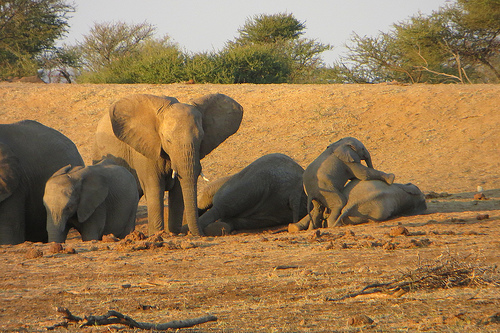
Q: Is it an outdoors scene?
A: Yes, it is outdoors.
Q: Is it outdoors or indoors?
A: It is outdoors.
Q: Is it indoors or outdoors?
A: It is outdoors.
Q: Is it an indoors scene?
A: No, it is outdoors.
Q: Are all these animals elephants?
A: Yes, all the animals are elephants.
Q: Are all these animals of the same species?
A: Yes, all the animals are elephants.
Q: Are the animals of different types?
A: No, all the animals are elephants.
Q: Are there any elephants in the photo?
A: Yes, there is an elephant.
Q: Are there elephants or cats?
A: Yes, there is an elephant.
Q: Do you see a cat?
A: No, there are no cats.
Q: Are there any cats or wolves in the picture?
A: No, there are no cats or wolves.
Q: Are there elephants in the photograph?
A: Yes, there is an elephant.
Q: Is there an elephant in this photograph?
A: Yes, there is an elephant.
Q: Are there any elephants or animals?
A: Yes, there is an elephant.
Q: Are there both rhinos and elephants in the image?
A: No, there is an elephant but no rhinos.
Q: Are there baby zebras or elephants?
A: Yes, there is a baby elephant.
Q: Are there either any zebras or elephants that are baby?
A: Yes, the elephant is a baby.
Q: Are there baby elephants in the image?
A: Yes, there is a baby elephant.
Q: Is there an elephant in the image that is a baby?
A: Yes, there is an elephant that is a baby.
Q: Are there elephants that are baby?
A: Yes, there is an elephant that is a baby.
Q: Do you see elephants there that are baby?
A: Yes, there is an elephant that is a baby.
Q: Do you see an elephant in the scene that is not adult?
A: Yes, there is an baby elephant.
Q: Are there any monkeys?
A: No, there are no monkeys.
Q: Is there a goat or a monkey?
A: No, there are no monkeys or goats.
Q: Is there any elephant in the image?
A: Yes, there is an elephant.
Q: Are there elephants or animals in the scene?
A: Yes, there is an elephant.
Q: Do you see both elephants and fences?
A: No, there is an elephant but no fences.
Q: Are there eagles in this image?
A: No, there are no eagles.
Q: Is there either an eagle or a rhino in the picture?
A: No, there are no eagles or rhinos.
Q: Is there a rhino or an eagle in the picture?
A: No, there are no eagles or rhinos.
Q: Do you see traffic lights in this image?
A: No, there are no traffic lights.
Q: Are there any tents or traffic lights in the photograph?
A: No, there are no traffic lights or tents.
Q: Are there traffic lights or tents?
A: No, there are no traffic lights or tents.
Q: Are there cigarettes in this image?
A: No, there are no cigarettes.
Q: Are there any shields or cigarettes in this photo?
A: No, there are no cigarettes or shields.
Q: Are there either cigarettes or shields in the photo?
A: No, there are no cigarettes or shields.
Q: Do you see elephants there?
A: Yes, there is an elephant.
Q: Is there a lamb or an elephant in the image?
A: Yes, there is an elephant.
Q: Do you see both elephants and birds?
A: No, there is an elephant but no birds.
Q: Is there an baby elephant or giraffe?
A: Yes, there is a baby elephant.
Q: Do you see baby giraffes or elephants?
A: Yes, there is a baby elephant.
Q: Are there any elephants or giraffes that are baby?
A: Yes, the elephant is a baby.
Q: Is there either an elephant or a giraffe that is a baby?
A: Yes, the elephant is a baby.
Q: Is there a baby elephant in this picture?
A: Yes, there is a baby elephant.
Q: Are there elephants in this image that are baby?
A: Yes, there is an elephant that is a baby.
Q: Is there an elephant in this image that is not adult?
A: Yes, there is an baby elephant.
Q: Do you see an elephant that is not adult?
A: Yes, there is an baby elephant.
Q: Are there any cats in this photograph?
A: No, there are no cats.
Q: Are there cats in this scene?
A: No, there are no cats.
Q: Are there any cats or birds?
A: No, there are no cats or birds.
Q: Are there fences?
A: No, there are no fences.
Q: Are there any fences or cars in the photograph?
A: No, there are no fences or cars.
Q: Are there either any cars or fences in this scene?
A: No, there are no fences or cars.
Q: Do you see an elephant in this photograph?
A: Yes, there is an elephant.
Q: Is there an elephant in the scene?
A: Yes, there is an elephant.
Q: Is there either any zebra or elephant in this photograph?
A: Yes, there is an elephant.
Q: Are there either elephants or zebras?
A: Yes, there is an elephant.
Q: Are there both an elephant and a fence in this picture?
A: No, there is an elephant but no fences.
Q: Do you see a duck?
A: No, there are no ducks.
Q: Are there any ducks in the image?
A: No, there are no ducks.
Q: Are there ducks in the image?
A: No, there are no ducks.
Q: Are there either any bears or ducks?
A: No, there are no ducks or bears.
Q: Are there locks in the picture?
A: No, there are no locks.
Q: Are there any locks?
A: No, there are no locks.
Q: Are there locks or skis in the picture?
A: No, there are no locks or skis.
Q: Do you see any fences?
A: No, there are no fences.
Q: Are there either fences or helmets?
A: No, there are no fences or helmets.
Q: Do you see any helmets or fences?
A: No, there are no fences or helmets.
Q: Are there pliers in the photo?
A: No, there are no pliers.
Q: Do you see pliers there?
A: No, there are no pliers.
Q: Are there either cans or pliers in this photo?
A: No, there are no pliers or cans.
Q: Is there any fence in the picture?
A: No, there are no fences.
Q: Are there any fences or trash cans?
A: No, there are no fences or trash cans.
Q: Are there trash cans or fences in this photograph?
A: No, there are no fences or trash cans.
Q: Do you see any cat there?
A: No, there are no cats.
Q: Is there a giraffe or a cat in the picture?
A: No, there are no cats or giraffes.